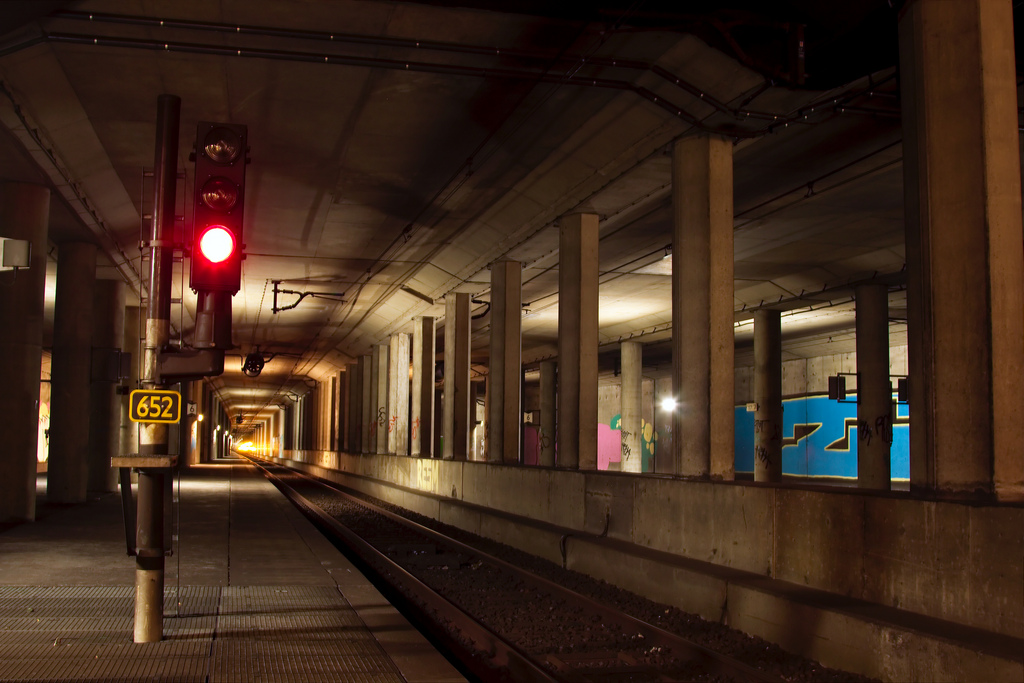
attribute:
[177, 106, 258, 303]
traffic light — red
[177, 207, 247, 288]
light — red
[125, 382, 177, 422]
number — yellow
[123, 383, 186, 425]
sign — black, yellow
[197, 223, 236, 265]
light — red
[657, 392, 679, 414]
light — white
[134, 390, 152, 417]
number — yellow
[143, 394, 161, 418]
number — yellow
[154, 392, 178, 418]
number — yellow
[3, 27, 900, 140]
pipe — black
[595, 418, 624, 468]
paint — pink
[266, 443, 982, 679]
barrier — concrete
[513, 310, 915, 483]
wall — cement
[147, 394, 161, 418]
number — yellow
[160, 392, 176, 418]
number — yellow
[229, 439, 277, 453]
light — yellow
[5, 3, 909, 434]
ceiling — cement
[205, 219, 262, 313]
light — red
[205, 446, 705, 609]
tracks — double metal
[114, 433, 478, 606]
subway platform — concrete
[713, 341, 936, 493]
graffiti — blue black and white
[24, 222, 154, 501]
plinth — support